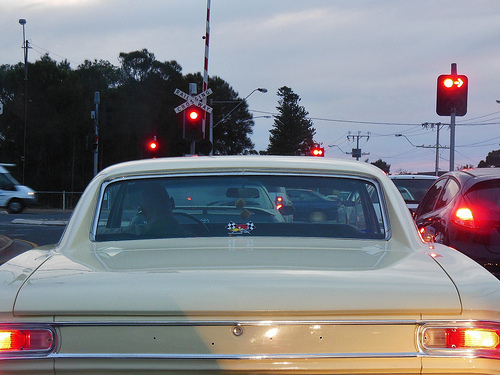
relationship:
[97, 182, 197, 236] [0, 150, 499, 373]
man in car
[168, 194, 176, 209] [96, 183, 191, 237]
ear of man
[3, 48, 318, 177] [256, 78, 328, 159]
leaves on tree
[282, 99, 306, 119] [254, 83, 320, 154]
leaves on tree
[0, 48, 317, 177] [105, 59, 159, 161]
leaves on tree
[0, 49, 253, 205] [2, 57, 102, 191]
leaves on tree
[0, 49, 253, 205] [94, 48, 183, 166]
leaves on tree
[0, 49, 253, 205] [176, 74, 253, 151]
leaves on tree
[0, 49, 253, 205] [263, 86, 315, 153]
leaves on tree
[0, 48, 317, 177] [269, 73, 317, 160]
leaves on tree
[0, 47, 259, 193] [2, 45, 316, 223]
leaves on trees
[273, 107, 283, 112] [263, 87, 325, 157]
leaf on tree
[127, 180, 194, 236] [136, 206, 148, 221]
man has ear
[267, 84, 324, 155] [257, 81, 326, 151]
leaves on tree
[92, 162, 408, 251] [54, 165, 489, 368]
window on car